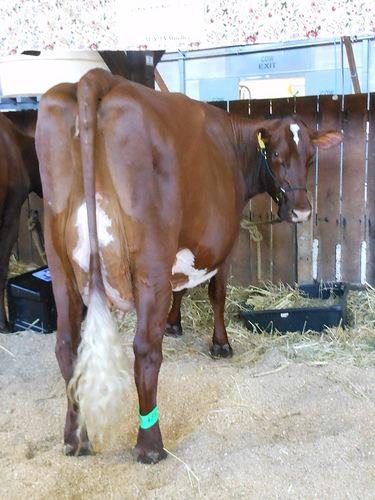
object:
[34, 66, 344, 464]
cow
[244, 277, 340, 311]
hay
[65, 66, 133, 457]
tail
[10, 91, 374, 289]
fence